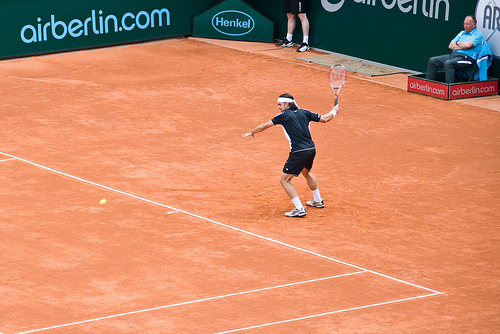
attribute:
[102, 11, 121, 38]
letter — blue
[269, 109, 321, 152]
shirt — black, navy blue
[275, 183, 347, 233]
socks — white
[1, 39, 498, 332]
dirt — reddish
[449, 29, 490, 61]
shirt — blue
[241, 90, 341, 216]
man — tennis playing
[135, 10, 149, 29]
letter — blue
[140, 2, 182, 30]
letter — blue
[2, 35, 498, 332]
tennis court — large, clay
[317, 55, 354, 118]
racket — Red, white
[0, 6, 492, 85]
wall — court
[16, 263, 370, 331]
line — white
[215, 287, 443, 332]
line — white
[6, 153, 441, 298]
line — white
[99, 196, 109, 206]
tennis ball — yellow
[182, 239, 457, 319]
line — white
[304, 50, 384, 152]
tennis racket — red, white, black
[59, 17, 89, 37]
letter — blue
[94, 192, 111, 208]
ball — lime green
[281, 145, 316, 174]
shorts — black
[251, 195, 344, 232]
socks — white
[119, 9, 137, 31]
letter — blue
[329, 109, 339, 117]
wristband — white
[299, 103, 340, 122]
arm — playes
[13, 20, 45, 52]
letter — blue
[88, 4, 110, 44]
letter — blue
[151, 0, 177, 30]
letter — blue